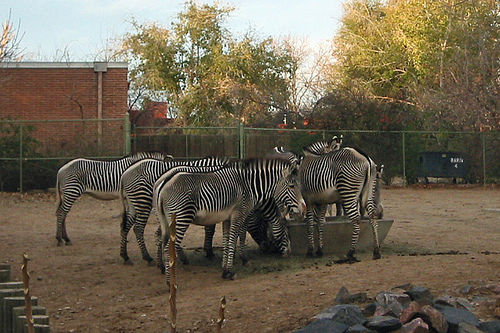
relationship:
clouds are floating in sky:
[250, 4, 307, 31] [3, 0, 329, 59]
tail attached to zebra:
[151, 181, 174, 250] [131, 158, 301, 271]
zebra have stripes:
[297, 134, 381, 264] [210, 174, 235, 218]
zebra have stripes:
[297, 134, 381, 264] [205, 172, 239, 212]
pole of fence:
[235, 119, 248, 160] [0, 109, 484, 192]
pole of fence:
[397, 130, 411, 186] [0, 109, 484, 192]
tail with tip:
[118, 182, 130, 229] [120, 210, 128, 235]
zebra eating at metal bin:
[297, 133, 391, 264] [275, 210, 392, 259]